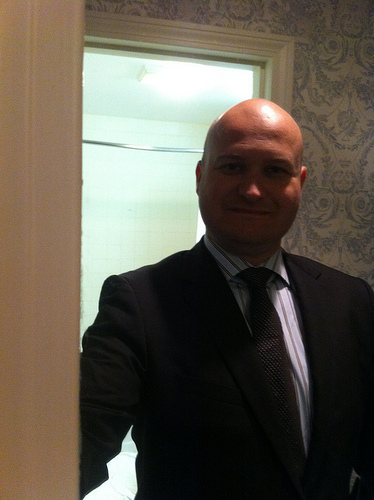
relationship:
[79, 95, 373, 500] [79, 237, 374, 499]
man wearing suit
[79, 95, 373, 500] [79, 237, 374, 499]
man wearing jacket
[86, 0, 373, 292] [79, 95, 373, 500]
wall behind man